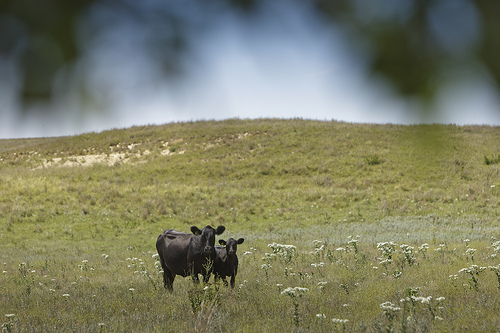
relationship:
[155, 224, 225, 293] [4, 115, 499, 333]
cows in field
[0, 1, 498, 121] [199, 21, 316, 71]
sky has patch blue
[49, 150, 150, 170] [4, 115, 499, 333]
dirt on hill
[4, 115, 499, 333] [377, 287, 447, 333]
field with flowers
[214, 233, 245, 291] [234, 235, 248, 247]
cow has right ear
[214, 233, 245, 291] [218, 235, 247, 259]
cow has head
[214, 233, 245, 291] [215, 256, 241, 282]
cow has body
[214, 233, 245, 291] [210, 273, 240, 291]
cow has legs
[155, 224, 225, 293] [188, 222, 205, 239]
cows has left ear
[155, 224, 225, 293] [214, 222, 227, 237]
cows has right ear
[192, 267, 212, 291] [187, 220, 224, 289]
legs on front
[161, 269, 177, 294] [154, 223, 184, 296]
legs on back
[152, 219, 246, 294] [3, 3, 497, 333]
cows looking towards camera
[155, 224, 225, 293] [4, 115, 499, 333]
cows on field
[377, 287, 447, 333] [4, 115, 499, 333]
flowers in a field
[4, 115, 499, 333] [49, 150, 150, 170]
hill has dirt patch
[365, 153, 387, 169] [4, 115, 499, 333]
brush on hill